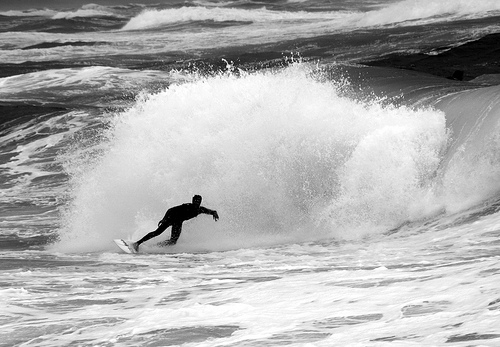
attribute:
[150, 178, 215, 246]
man — surfing, white, splashing, wet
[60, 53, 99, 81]
water — blue, splashing, crashing, rough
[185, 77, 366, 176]
waves — crashing, white